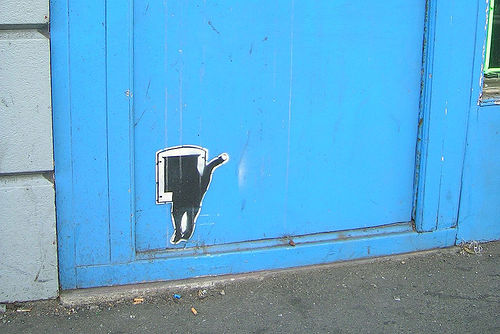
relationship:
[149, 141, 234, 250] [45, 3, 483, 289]
painting on door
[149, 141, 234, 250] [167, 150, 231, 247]
painting of cat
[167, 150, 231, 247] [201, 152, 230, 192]
cat has tail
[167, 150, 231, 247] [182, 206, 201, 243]
cat has leg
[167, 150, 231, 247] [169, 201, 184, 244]
cat has leg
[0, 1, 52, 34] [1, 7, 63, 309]
brick of wall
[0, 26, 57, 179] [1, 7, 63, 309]
brick of wall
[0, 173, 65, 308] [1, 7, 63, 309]
brick of wall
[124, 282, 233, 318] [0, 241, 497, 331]
garbage on ground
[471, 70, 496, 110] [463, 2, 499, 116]
corner of window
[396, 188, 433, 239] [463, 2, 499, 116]
corner of window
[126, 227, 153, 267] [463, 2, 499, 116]
corner of window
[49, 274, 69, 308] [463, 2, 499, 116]
corner of window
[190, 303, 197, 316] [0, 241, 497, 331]
cigarette butt on ground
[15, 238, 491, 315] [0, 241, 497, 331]
trash on ground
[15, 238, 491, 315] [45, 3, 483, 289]
trash outside door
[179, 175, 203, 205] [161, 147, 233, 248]
backside of cat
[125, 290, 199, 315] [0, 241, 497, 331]
cigarette butts on ground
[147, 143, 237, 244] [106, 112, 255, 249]
backside on cat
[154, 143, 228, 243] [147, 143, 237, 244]
picture of backside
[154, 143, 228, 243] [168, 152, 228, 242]
picture of a cat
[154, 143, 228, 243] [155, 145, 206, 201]
picture of a pet door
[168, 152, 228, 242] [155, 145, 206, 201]
cat entering pet door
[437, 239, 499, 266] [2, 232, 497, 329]
garbage on street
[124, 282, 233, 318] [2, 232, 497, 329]
garbage on street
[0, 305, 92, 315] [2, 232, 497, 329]
garbage on street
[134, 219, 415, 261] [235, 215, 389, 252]
dirt on door frame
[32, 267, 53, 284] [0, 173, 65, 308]
marks on brick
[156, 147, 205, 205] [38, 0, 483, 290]
opening on door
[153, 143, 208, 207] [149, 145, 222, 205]
white border on opening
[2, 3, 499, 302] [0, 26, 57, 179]
wall made of brick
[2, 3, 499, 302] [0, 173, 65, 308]
wall made of brick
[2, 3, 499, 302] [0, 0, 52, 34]
wall made of brick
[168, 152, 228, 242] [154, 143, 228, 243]
cat on picture